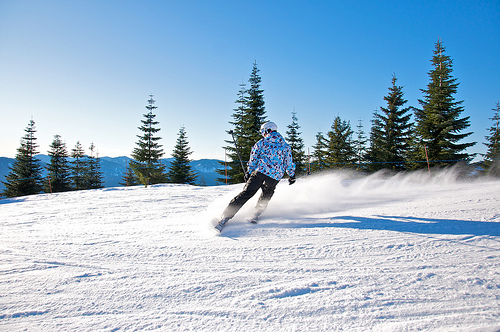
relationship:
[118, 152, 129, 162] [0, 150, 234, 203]
top on mountain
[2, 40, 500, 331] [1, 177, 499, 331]
landscape has snow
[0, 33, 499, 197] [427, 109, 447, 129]
pine trees have pine needles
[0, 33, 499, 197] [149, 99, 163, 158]
pine trees have branches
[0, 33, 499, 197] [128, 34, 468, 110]
pine trees have tree tops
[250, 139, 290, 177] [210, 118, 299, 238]
back of skiier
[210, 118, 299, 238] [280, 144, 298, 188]
skiier has an arm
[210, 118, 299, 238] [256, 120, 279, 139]
skiier wearing a helmet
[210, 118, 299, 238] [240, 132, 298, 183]
skiier wearing a jacket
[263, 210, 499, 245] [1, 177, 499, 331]
shadow on snow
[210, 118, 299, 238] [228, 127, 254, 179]
skiier has poles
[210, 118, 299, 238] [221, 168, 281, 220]
skiier wearing black pants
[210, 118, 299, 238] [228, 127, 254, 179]
skiier holding ski pole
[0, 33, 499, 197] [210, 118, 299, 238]
pine trees in front of skiier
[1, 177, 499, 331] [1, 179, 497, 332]
snow on ground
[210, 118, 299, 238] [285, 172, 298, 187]
skiier wearing black gloves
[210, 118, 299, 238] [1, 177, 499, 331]
skier spraying snow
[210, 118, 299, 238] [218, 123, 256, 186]
skiier has a pole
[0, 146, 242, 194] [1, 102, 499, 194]
hills in distance